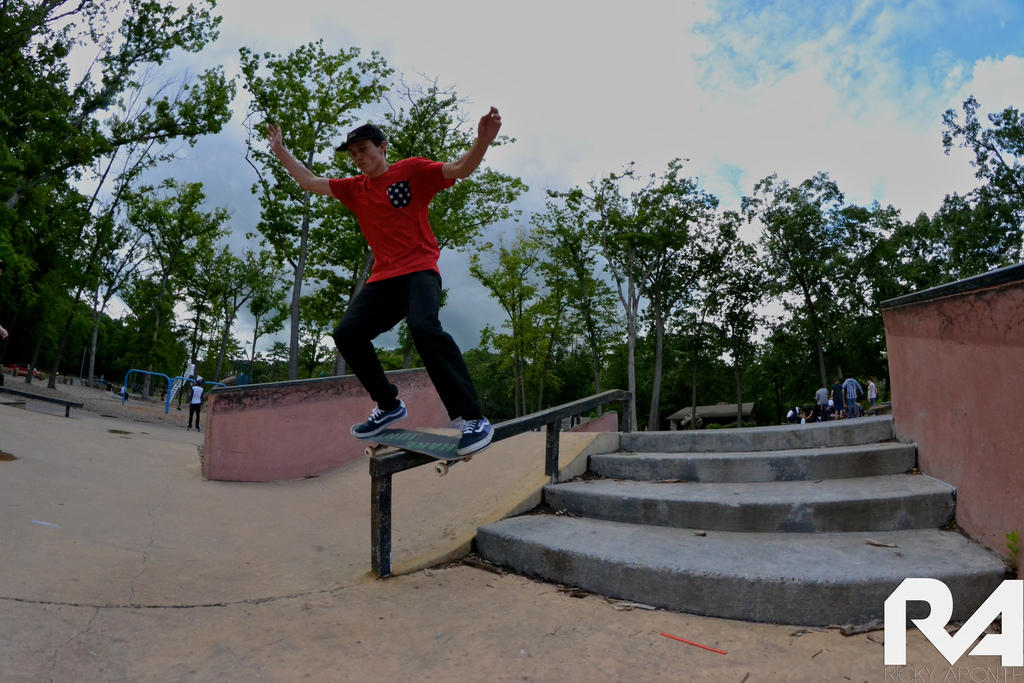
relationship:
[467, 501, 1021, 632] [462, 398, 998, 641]
step on a stairway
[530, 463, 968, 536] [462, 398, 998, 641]
step on a stairway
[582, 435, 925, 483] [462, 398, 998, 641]
step on a stairway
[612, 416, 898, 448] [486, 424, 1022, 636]
step on a stairway